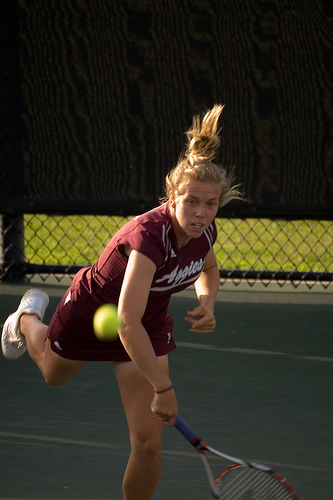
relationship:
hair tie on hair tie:
[155, 381, 178, 396] [154, 383, 174, 394]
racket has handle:
[173, 413, 300, 498] [173, 417, 209, 453]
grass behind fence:
[24, 214, 331, 273] [1, 205, 332, 293]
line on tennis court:
[174, 340, 331, 363] [2, 280, 331, 499]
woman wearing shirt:
[2, 100, 251, 499] [78, 199, 220, 311]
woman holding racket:
[2, 100, 251, 499] [173, 413, 300, 498]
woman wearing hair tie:
[2, 100, 251, 499] [155, 381, 178, 396]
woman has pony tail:
[2, 100, 251, 499] [185, 103, 222, 164]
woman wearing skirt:
[2, 100, 251, 499] [45, 267, 181, 361]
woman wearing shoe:
[2, 100, 251, 499] [2, 289, 53, 362]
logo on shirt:
[152, 257, 206, 291] [78, 199, 220, 311]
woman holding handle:
[2, 100, 251, 499] [173, 417, 209, 453]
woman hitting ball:
[2, 100, 251, 499] [91, 303, 127, 339]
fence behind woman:
[1, 205, 332, 293] [2, 100, 251, 499]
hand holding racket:
[151, 389, 183, 425] [173, 413, 300, 498]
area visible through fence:
[14, 193, 332, 275] [18, 202, 331, 271]